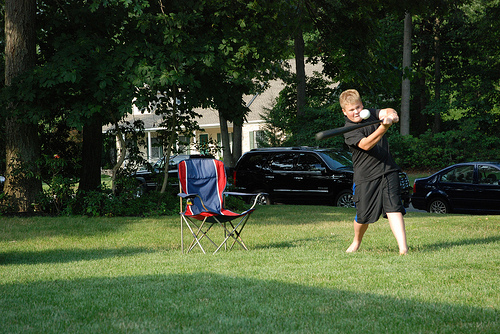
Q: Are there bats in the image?
A: Yes, there is a bat.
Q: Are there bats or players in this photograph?
A: Yes, there is a bat.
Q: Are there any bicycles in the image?
A: No, there are no bicycles.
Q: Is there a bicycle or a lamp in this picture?
A: No, there are no bicycles or lamps.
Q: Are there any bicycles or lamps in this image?
A: No, there are no bicycles or lamps.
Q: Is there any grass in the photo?
A: Yes, there is grass.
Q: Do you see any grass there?
A: Yes, there is grass.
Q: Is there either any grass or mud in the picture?
A: Yes, there is grass.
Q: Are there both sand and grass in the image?
A: No, there is grass but no sand.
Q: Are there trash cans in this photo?
A: No, there are no trash cans.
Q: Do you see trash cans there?
A: No, there are no trash cans.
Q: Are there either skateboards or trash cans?
A: No, there are no trash cans or skateboards.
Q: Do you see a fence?
A: No, there are no fences.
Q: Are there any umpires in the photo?
A: No, there are no umpires.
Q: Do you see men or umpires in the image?
A: No, there are no umpires or men.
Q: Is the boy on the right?
A: Yes, the boy is on the right of the image.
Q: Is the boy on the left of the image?
A: No, the boy is on the right of the image.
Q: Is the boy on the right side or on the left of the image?
A: The boy is on the right of the image.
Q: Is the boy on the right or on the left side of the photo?
A: The boy is on the right of the image.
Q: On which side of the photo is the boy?
A: The boy is on the right of the image.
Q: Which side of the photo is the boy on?
A: The boy is on the right of the image.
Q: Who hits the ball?
A: The boy hits the ball.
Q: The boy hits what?
A: The boy hits the ball.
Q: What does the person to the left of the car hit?
A: The boy hits the ball.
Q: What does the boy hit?
A: The boy hits the ball.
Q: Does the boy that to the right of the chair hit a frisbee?
A: No, the boy hits the ball.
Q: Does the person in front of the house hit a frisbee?
A: No, the boy hits the ball.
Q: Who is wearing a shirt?
A: The boy is wearing a shirt.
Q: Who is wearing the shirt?
A: The boy is wearing a shirt.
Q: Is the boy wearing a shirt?
A: Yes, the boy is wearing a shirt.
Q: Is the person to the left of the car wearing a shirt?
A: Yes, the boy is wearing a shirt.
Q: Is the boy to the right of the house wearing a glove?
A: No, the boy is wearing a shirt.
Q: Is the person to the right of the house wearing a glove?
A: No, the boy is wearing a shirt.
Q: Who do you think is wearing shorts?
A: The boy is wearing shorts.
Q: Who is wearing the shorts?
A: The boy is wearing shorts.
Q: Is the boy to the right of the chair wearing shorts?
A: Yes, the boy is wearing shorts.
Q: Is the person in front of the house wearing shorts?
A: Yes, the boy is wearing shorts.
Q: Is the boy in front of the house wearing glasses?
A: No, the boy is wearing shorts.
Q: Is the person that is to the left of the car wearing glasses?
A: No, the boy is wearing shorts.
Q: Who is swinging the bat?
A: The boy is swinging the bat.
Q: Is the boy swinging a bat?
A: Yes, the boy is swinging a bat.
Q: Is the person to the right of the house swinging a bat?
A: Yes, the boy is swinging a bat.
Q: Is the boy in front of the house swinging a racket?
A: No, the boy is swinging a bat.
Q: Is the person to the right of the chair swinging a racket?
A: No, the boy is swinging a bat.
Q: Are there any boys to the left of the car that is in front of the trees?
A: Yes, there is a boy to the left of the car.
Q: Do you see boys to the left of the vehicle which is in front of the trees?
A: Yes, there is a boy to the left of the car.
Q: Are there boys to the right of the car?
A: No, the boy is to the left of the car.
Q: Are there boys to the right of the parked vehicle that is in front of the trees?
A: No, the boy is to the left of the car.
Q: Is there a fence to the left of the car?
A: No, there is a boy to the left of the car.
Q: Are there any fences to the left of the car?
A: No, there is a boy to the left of the car.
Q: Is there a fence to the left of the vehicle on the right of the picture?
A: No, there is a boy to the left of the car.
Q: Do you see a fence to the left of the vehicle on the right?
A: No, there is a boy to the left of the car.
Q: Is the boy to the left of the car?
A: Yes, the boy is to the left of the car.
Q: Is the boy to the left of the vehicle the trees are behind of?
A: Yes, the boy is to the left of the car.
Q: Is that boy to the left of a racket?
A: No, the boy is to the left of the car.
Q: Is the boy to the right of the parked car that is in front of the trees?
A: No, the boy is to the left of the car.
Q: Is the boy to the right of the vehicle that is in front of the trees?
A: No, the boy is to the left of the car.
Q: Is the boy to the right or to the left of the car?
A: The boy is to the left of the car.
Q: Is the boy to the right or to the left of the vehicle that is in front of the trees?
A: The boy is to the left of the car.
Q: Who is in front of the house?
A: The boy is in front of the house.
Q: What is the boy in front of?
A: The boy is in front of the house.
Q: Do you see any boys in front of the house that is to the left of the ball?
A: Yes, there is a boy in front of the house.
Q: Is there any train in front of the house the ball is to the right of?
A: No, there is a boy in front of the house.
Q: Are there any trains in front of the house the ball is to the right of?
A: No, there is a boy in front of the house.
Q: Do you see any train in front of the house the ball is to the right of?
A: No, there is a boy in front of the house.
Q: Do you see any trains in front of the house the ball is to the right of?
A: No, there is a boy in front of the house.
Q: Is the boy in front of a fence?
A: No, the boy is in front of the house.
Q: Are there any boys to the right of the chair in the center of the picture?
A: Yes, there is a boy to the right of the chair.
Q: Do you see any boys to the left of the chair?
A: No, the boy is to the right of the chair.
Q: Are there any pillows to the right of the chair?
A: No, there is a boy to the right of the chair.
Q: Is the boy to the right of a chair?
A: Yes, the boy is to the right of a chair.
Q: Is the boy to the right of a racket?
A: No, the boy is to the right of a chair.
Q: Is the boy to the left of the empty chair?
A: No, the boy is to the right of the chair.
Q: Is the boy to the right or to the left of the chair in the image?
A: The boy is to the right of the chair.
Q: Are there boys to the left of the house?
A: No, the boy is to the right of the house.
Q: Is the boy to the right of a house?
A: Yes, the boy is to the right of a house.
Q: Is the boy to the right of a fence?
A: No, the boy is to the right of a house.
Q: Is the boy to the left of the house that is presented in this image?
A: No, the boy is to the right of the house.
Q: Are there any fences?
A: No, there are no fences.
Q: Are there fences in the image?
A: No, there are no fences.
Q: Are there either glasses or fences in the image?
A: No, there are no fences or glasses.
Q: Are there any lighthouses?
A: No, there are no lighthouses.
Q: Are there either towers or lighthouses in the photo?
A: No, there are no lighthouses or towers.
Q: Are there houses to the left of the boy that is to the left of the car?
A: Yes, there is a house to the left of the boy.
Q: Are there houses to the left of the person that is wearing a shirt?
A: Yes, there is a house to the left of the boy.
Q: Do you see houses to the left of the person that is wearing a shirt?
A: Yes, there is a house to the left of the boy.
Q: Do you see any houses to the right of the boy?
A: No, the house is to the left of the boy.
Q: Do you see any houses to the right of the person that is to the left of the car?
A: No, the house is to the left of the boy.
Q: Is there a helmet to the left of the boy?
A: No, there is a house to the left of the boy.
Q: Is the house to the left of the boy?
A: Yes, the house is to the left of the boy.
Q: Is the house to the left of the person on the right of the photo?
A: Yes, the house is to the left of the boy.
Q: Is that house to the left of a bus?
A: No, the house is to the left of the boy.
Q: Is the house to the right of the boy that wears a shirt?
A: No, the house is to the left of the boy.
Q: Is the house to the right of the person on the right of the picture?
A: No, the house is to the left of the boy.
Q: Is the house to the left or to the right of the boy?
A: The house is to the left of the boy.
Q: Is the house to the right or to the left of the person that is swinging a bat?
A: The house is to the left of the boy.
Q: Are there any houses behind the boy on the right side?
A: Yes, there is a house behind the boy.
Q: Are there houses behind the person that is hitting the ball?
A: Yes, there is a house behind the boy.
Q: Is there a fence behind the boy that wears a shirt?
A: No, there is a house behind the boy.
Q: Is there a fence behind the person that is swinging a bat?
A: No, there is a house behind the boy.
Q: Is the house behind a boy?
A: Yes, the house is behind a boy.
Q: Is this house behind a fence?
A: No, the house is behind a boy.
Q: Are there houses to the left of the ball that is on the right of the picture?
A: Yes, there is a house to the left of the ball.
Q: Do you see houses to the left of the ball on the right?
A: Yes, there is a house to the left of the ball.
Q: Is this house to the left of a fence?
A: No, the house is to the left of a ball.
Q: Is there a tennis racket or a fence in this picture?
A: No, there are no fences or rackets.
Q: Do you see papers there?
A: No, there are no papers.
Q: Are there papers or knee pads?
A: No, there are no papers or knee pads.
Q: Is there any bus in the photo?
A: No, there are no buses.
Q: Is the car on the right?
A: Yes, the car is on the right of the image.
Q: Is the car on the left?
A: No, the car is on the right of the image.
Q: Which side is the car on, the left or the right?
A: The car is on the right of the image.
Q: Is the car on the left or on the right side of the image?
A: The car is on the right of the image.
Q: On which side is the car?
A: The car is on the right of the image.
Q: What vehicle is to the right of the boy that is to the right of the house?
A: The vehicle is a car.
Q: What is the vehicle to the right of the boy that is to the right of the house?
A: The vehicle is a car.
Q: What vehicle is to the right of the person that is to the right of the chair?
A: The vehicle is a car.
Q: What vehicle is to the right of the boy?
A: The vehicle is a car.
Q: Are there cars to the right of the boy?
A: Yes, there is a car to the right of the boy.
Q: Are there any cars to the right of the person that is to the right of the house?
A: Yes, there is a car to the right of the boy.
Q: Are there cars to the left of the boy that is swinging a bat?
A: No, the car is to the right of the boy.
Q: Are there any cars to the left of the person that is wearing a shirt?
A: No, the car is to the right of the boy.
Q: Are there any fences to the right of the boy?
A: No, there is a car to the right of the boy.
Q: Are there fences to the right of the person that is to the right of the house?
A: No, there is a car to the right of the boy.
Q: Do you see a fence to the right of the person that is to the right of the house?
A: No, there is a car to the right of the boy.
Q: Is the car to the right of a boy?
A: Yes, the car is to the right of a boy.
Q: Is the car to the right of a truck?
A: No, the car is to the right of a boy.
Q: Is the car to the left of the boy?
A: No, the car is to the right of the boy.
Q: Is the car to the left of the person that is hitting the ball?
A: No, the car is to the right of the boy.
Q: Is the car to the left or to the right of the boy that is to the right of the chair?
A: The car is to the right of the boy.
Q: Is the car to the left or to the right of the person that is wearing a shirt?
A: The car is to the right of the boy.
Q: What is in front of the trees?
A: The car is in front of the trees.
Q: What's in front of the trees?
A: The car is in front of the trees.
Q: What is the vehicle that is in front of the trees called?
A: The vehicle is a car.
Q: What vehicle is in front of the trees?
A: The vehicle is a car.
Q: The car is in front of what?
A: The car is in front of the trees.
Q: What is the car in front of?
A: The car is in front of the trees.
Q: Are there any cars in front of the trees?
A: Yes, there is a car in front of the trees.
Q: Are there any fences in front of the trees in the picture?
A: No, there is a car in front of the trees.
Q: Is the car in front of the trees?
A: Yes, the car is in front of the trees.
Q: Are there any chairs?
A: Yes, there is a chair.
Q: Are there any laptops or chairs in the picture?
A: Yes, there is a chair.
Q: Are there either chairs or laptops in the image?
A: Yes, there is a chair.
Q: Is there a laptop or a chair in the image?
A: Yes, there is a chair.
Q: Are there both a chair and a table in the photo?
A: No, there is a chair but no tables.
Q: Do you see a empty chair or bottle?
A: Yes, there is an empty chair.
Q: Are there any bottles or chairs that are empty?
A: Yes, the chair is empty.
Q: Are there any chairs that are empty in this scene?
A: Yes, there is an empty chair.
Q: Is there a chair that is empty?
A: Yes, there is a chair that is empty.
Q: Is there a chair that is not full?
A: Yes, there is a empty chair.